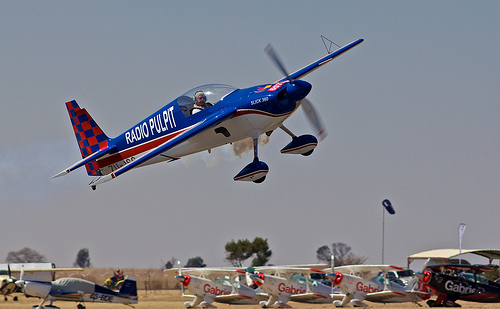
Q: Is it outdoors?
A: Yes, it is outdoors.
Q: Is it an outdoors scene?
A: Yes, it is outdoors.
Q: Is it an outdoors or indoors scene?
A: It is outdoors.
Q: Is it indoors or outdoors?
A: It is outdoors.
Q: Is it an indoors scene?
A: No, it is outdoors.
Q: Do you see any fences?
A: No, there are no fences.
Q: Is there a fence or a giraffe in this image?
A: No, there are no fences or giraffes.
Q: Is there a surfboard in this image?
A: No, there are no surfboards.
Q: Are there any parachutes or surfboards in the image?
A: No, there are no surfboards or parachutes.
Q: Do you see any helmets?
A: No, there are no helmets.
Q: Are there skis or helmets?
A: No, there are no helmets or skis.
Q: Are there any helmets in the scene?
A: No, there are no helmets.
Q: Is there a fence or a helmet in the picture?
A: No, there are no helmets or fences.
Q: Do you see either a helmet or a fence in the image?
A: No, there are no helmets or fences.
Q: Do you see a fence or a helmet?
A: No, there are no helmets or fences.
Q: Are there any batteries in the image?
A: No, there are no batteries.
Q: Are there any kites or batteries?
A: No, there are no batteries or kites.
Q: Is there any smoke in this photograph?
A: Yes, there is smoke.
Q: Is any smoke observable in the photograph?
A: Yes, there is smoke.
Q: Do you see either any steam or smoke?
A: Yes, there is smoke.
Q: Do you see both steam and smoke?
A: No, there is smoke but no steam.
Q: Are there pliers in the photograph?
A: No, there are no pliers.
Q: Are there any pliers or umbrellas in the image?
A: No, there are no pliers or umbrellas.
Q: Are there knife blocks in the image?
A: No, there are no knife blocks.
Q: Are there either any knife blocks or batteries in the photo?
A: No, there are no knife blocks or batteries.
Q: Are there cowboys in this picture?
A: No, there are no cowboys.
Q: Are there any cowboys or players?
A: No, there are no cowboys or players.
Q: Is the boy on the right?
A: Yes, the boy is on the right of the image.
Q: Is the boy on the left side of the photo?
A: No, the boy is on the right of the image.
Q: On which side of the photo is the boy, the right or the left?
A: The boy is on the right of the image.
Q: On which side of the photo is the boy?
A: The boy is on the right of the image.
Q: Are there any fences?
A: No, there are no fences.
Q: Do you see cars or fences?
A: No, there are no fences or cars.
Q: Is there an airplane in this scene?
A: Yes, there is an airplane.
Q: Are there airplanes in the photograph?
A: Yes, there is an airplane.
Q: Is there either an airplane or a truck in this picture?
A: Yes, there is an airplane.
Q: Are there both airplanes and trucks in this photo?
A: No, there is an airplane but no trucks.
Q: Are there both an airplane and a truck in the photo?
A: No, there is an airplane but no trucks.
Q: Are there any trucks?
A: No, there are no trucks.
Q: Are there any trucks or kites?
A: No, there are no trucks or kites.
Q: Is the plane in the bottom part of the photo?
A: Yes, the plane is in the bottom of the image.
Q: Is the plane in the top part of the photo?
A: No, the plane is in the bottom of the image.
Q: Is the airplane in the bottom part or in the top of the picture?
A: The airplane is in the bottom of the image.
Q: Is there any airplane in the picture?
A: Yes, there is an airplane.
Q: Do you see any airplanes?
A: Yes, there is an airplane.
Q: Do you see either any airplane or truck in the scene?
A: Yes, there is an airplane.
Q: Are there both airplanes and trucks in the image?
A: No, there is an airplane but no trucks.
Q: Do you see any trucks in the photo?
A: No, there are no trucks.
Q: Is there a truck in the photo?
A: No, there are no trucks.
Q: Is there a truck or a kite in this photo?
A: No, there are no trucks or kites.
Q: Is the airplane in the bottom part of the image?
A: Yes, the airplane is in the bottom of the image.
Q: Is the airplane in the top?
A: No, the airplane is in the bottom of the image.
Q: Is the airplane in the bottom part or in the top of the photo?
A: The airplane is in the bottom of the image.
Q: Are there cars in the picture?
A: No, there are no cars.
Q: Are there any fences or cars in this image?
A: No, there are no cars or fences.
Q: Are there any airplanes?
A: Yes, there is an airplane.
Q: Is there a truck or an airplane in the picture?
A: Yes, there is an airplane.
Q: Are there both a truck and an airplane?
A: No, there is an airplane but no trucks.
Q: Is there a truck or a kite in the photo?
A: No, there are no trucks or kites.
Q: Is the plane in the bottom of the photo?
A: Yes, the plane is in the bottom of the image.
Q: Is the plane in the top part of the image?
A: No, the plane is in the bottom of the image.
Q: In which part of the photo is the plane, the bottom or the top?
A: The plane is in the bottom of the image.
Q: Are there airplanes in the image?
A: Yes, there is an airplane.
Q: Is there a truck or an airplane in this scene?
A: Yes, there is an airplane.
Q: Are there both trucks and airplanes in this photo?
A: No, there is an airplane but no trucks.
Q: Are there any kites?
A: No, there are no kites.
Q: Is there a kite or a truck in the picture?
A: No, there are no kites or trucks.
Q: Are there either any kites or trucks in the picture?
A: No, there are no kites or trucks.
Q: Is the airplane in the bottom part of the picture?
A: Yes, the airplane is in the bottom of the image.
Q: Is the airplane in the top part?
A: No, the airplane is in the bottom of the image.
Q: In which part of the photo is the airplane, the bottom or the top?
A: The airplane is in the bottom of the image.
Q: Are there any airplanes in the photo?
A: Yes, there is an airplane.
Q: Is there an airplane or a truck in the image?
A: Yes, there is an airplane.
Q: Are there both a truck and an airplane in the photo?
A: No, there is an airplane but no trucks.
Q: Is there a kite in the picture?
A: No, there are no kites.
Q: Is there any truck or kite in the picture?
A: No, there are no kites or trucks.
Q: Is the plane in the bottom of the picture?
A: Yes, the plane is in the bottom of the image.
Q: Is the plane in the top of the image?
A: No, the plane is in the bottom of the image.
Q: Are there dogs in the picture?
A: No, there are no dogs.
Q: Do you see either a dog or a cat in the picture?
A: No, there are no dogs or cats.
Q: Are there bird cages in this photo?
A: No, there are no bird cages.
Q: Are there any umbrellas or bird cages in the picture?
A: No, there are no bird cages or umbrellas.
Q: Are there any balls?
A: No, there are no balls.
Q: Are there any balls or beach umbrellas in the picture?
A: No, there are no balls or beach umbrellas.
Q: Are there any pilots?
A: Yes, there is a pilot.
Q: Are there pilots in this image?
A: Yes, there is a pilot.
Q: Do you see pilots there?
A: Yes, there is a pilot.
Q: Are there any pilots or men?
A: Yes, there is a pilot.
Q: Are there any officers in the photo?
A: No, there are no officers.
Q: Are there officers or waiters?
A: No, there are no officers or waiters.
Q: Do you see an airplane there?
A: Yes, there is an airplane.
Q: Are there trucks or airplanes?
A: Yes, there is an airplane.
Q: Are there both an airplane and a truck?
A: No, there is an airplane but no trucks.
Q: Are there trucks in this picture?
A: No, there are no trucks.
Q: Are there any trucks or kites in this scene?
A: No, there are no trucks or kites.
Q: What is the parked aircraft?
A: The aircraft is an airplane.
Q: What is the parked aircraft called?
A: The aircraft is an airplane.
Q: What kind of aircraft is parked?
A: The aircraft is an airplane.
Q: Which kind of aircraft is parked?
A: The aircraft is an airplane.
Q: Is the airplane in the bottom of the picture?
A: Yes, the airplane is in the bottom of the image.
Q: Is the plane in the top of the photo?
A: No, the plane is in the bottom of the image.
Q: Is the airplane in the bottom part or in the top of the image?
A: The airplane is in the bottom of the image.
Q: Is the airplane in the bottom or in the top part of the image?
A: The airplane is in the bottom of the image.